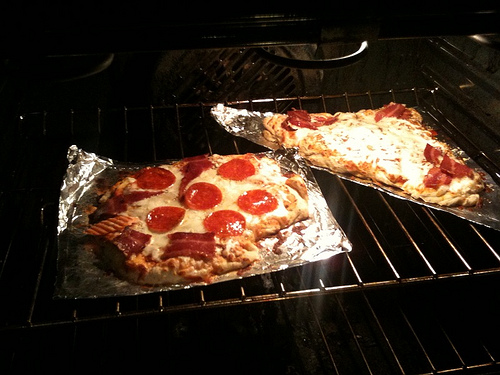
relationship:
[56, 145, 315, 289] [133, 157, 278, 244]
pizza has pepperoni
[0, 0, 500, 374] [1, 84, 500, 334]
oven has rack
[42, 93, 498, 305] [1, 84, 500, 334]
tinfoil on rack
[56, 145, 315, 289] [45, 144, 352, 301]
pizza on tinfoil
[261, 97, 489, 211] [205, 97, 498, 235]
pizza on tinfoil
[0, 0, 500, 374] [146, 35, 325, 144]
oven has fan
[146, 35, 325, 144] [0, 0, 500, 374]
fan at back of oven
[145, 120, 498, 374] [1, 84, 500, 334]
lower rack beneath rack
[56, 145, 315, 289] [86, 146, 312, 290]
pizza has crust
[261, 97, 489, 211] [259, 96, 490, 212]
pizza has crust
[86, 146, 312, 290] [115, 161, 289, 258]
crust has cheese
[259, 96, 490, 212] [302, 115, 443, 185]
crust has cheese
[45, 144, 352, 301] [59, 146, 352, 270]
tinfoil has reflected light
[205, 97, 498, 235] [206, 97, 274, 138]
tinfoil has reflected light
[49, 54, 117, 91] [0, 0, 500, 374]
hose inside oven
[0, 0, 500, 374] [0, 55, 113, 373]
oven has right wall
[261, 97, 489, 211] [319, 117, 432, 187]
pizza has ramen [?]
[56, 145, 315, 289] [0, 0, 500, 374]
pizza in oven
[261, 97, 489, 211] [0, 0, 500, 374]
pizza in oven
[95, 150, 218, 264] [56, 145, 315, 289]
bacon on pizza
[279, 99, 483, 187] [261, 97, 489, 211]
bacon on pizza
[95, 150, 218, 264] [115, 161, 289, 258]
bacon on cheese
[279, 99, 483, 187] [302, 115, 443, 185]
bacon on cheese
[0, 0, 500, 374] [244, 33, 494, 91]
oven has light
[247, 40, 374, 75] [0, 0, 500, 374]
heating coil in oven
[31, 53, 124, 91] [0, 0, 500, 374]
heating coil in oven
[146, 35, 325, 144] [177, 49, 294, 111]
fan has air vents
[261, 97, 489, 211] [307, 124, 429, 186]
pizza has no central meat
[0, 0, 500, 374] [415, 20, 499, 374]
oven has left wall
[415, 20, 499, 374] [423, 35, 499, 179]
left wall has grooves for racks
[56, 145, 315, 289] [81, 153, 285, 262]
pizza has toppings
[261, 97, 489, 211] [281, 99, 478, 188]
pizza has toppings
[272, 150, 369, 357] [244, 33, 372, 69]
rays of light from light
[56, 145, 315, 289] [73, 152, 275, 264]
pizza has pepperoni & bacon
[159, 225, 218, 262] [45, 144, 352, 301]
bacon melted on tinfoil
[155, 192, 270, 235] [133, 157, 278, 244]
grease atop pepperoni